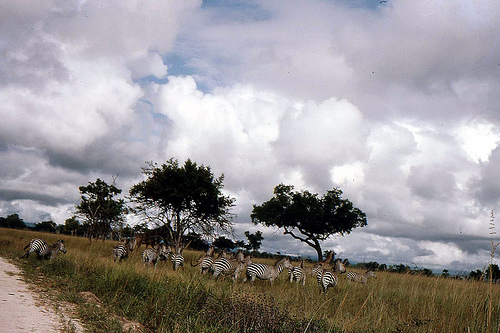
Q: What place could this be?
A: It is a field.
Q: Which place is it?
A: It is a field.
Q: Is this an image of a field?
A: Yes, it is showing a field.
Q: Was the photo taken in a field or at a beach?
A: It was taken at a field.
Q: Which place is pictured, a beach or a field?
A: It is a field.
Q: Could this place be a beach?
A: No, it is a field.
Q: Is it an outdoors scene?
A: Yes, it is outdoors.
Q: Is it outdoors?
A: Yes, it is outdoors.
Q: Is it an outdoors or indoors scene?
A: It is outdoors.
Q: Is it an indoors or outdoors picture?
A: It is outdoors.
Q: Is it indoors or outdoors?
A: It is outdoors.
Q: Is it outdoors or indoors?
A: It is outdoors.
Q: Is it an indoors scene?
A: No, it is outdoors.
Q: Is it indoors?
A: No, it is outdoors.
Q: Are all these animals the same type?
A: Yes, all the animals are zebras.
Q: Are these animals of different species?
A: No, all the animals are zebras.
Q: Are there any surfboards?
A: No, there are no surfboards.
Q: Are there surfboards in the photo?
A: No, there are no surfboards.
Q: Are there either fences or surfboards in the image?
A: No, there are no surfboards or fences.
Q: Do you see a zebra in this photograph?
A: Yes, there are zebras.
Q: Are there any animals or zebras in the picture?
A: Yes, there are zebras.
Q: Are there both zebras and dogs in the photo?
A: No, there are zebras but no dogs.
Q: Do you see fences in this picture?
A: No, there are no fences.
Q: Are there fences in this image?
A: No, there are no fences.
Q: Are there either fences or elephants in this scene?
A: No, there are no fences or elephants.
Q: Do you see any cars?
A: No, there are no cars.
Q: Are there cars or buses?
A: No, there are no cars or buses.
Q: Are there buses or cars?
A: No, there are no cars or buses.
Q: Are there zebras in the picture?
A: Yes, there is a zebra.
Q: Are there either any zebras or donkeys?
A: Yes, there is a zebra.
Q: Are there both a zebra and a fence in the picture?
A: No, there is a zebra but no fences.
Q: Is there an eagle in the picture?
A: No, there are no eagles.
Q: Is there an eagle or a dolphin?
A: No, there are no eagles or dolphins.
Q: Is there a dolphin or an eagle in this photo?
A: No, there are no eagles or dolphins.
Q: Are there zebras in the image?
A: Yes, there is a zebra.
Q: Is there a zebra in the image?
A: Yes, there is a zebra.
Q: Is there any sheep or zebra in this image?
A: Yes, there is a zebra.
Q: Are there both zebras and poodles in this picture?
A: No, there is a zebra but no poodles.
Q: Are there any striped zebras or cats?
A: Yes, there is a striped zebra.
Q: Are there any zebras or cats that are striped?
A: Yes, the zebra is striped.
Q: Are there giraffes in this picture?
A: No, there are no giraffes.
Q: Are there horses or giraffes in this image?
A: No, there are no giraffes or horses.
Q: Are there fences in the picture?
A: No, there are no fences.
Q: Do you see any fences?
A: No, there are no fences.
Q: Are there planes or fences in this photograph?
A: No, there are no fences or planes.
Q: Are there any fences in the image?
A: No, there are no fences.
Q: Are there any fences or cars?
A: No, there are no fences or cars.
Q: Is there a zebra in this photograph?
A: Yes, there is a zebra.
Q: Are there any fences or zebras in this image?
A: Yes, there is a zebra.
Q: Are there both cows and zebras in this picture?
A: No, there is a zebra but no cows.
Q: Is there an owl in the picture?
A: No, there are no owls.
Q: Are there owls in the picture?
A: No, there are no owls.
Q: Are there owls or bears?
A: No, there are no owls or bears.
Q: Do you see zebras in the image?
A: Yes, there is a zebra.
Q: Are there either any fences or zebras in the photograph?
A: Yes, there is a zebra.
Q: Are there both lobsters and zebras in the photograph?
A: No, there is a zebra but no lobsters.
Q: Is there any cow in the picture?
A: No, there are no cows.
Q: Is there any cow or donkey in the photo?
A: No, there are no cows or donkeys.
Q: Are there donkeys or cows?
A: No, there are no cows or donkeys.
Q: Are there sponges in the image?
A: No, there are no sponges.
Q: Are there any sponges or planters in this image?
A: No, there are no sponges or planters.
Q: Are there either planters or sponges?
A: No, there are no sponges or planters.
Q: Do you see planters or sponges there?
A: No, there are no sponges or planters.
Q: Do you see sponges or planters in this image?
A: No, there are no sponges or planters.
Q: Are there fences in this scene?
A: No, there are no fences.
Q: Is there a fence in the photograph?
A: No, there are no fences.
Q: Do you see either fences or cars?
A: No, there are no fences or cars.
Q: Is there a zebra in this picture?
A: Yes, there are zebras.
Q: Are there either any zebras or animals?
A: Yes, there are zebras.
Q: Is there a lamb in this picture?
A: No, there are no lambs.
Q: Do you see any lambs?
A: No, there are no lambs.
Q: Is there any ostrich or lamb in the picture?
A: No, there are no lambs or ostriches.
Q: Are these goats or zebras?
A: These are zebras.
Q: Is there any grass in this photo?
A: Yes, there is grass.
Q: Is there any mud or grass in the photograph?
A: Yes, there is grass.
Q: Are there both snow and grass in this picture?
A: No, there is grass but no snow.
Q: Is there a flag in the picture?
A: No, there are no flags.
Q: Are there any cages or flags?
A: No, there are no flags or cages.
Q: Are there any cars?
A: No, there are no cars.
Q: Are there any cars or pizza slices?
A: No, there are no cars or pizza slices.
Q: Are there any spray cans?
A: No, there are no spray cans.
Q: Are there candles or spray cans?
A: No, there are no spray cans or candles.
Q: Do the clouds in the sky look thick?
A: Yes, the clouds are thick.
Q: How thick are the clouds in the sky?
A: The clouds are thick.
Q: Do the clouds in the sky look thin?
A: No, the clouds are thick.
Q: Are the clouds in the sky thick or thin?
A: The clouds are thick.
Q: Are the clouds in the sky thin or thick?
A: The clouds are thick.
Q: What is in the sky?
A: The clouds are in the sky.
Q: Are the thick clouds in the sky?
A: Yes, the clouds are in the sky.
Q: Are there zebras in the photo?
A: Yes, there are zebras.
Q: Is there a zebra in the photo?
A: Yes, there are zebras.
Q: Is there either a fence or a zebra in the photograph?
A: Yes, there are zebras.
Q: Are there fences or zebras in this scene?
A: Yes, there are zebras.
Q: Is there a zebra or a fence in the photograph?
A: Yes, there are zebras.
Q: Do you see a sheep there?
A: No, there is no sheep.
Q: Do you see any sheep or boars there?
A: No, there are no sheep or boars.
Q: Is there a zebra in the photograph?
A: Yes, there is a zebra.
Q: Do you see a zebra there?
A: Yes, there is a zebra.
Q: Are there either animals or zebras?
A: Yes, there is a zebra.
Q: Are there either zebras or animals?
A: Yes, there is a zebra.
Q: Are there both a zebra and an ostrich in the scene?
A: No, there is a zebra but no ostriches.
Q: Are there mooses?
A: No, there are no mooses.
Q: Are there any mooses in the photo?
A: No, there are no mooses.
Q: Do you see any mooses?
A: No, there are no mooses.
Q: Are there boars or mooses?
A: No, there are no mooses or boars.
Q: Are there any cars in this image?
A: No, there are no cars.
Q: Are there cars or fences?
A: No, there are no cars or fences.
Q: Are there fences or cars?
A: No, there are no cars or fences.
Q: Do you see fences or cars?
A: No, there are no cars or fences.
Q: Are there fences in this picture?
A: No, there are no fences.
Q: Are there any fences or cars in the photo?
A: No, there are no fences or cars.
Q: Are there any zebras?
A: Yes, there is a zebra.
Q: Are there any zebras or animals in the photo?
A: Yes, there is a zebra.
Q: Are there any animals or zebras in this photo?
A: Yes, there is a zebra.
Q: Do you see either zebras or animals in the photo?
A: Yes, there is a zebra.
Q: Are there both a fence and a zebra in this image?
A: No, there is a zebra but no fences.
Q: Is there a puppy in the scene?
A: No, there are no puppys.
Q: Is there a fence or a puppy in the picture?
A: No, there are no puppys or fences.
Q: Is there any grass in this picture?
A: Yes, there is grass.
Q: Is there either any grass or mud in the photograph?
A: Yes, there is grass.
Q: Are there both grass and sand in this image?
A: No, there is grass but no sand.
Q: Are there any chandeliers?
A: No, there are no chandeliers.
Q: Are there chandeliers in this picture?
A: No, there are no chandeliers.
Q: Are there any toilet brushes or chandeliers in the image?
A: No, there are no chandeliers or toilet brushes.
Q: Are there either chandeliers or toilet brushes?
A: No, there are no chandeliers or toilet brushes.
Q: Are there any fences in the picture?
A: No, there are no fences.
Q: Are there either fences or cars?
A: No, there are no fences or cars.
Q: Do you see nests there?
A: No, there are no nests.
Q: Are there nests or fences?
A: No, there are no nests or fences.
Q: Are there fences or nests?
A: No, there are no nests or fences.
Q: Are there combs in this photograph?
A: No, there are no combs.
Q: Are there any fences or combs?
A: No, there are no combs or fences.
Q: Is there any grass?
A: Yes, there is grass.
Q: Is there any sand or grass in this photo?
A: Yes, there is grass.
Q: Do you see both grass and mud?
A: No, there is grass but no mud.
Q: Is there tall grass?
A: Yes, there is tall grass.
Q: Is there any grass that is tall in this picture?
A: Yes, there is tall grass.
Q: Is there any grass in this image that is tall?
A: Yes, there is grass that is tall.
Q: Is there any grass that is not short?
A: Yes, there is tall grass.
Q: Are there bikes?
A: No, there are no bikes.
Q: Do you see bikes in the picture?
A: No, there are no bikes.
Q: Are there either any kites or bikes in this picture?
A: No, there are no bikes or kites.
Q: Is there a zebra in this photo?
A: Yes, there is a zebra.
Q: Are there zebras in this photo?
A: Yes, there is a zebra.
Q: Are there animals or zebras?
A: Yes, there is a zebra.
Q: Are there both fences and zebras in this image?
A: No, there is a zebra but no fences.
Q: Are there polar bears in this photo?
A: No, there are no polar bears.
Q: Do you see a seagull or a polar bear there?
A: No, there are no polar bears or seagulls.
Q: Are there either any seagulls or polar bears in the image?
A: No, there are no polar bears or seagulls.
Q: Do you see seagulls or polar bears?
A: No, there are no polar bears or seagulls.